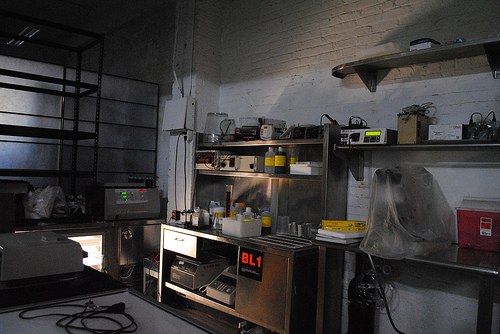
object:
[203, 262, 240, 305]
cash register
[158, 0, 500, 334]
brick wall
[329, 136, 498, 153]
shelf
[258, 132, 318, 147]
shelf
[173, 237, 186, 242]
handle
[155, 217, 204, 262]
drawer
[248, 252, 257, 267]
orange letter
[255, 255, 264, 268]
orange letter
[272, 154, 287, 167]
labels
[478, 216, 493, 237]
caution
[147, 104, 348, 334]
workstation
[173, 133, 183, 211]
chords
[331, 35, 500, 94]
high shelf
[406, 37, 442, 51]
item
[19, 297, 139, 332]
cable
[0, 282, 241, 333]
floor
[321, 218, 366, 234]
yellow box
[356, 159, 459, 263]
tarp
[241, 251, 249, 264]
capital letters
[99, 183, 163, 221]
machine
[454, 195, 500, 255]
box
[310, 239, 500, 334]
table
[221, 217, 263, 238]
item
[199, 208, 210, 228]
item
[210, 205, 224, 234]
item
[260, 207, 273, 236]
item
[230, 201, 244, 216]
item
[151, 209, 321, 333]
counter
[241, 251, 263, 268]
sign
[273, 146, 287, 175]
bottles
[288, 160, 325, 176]
box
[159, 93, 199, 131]
power box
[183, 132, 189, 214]
cords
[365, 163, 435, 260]
item